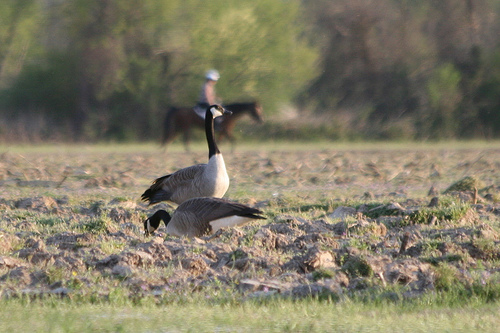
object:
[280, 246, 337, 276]
rock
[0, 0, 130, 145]
tree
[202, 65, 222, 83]
helmet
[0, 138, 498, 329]
grass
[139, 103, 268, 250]
goose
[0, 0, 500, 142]
trees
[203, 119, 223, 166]
neck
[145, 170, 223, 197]
feather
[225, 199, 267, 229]
tail wing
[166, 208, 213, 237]
wing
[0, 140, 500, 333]
ground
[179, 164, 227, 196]
chest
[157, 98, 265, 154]
horse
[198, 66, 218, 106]
man